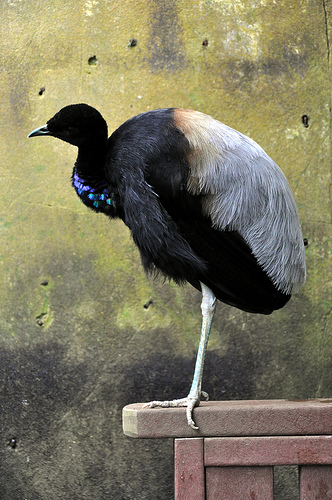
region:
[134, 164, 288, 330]
bird has black feathers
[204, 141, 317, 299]
bird has grey feathers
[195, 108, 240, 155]
bird has white feathers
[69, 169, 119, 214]
bird has blue feathers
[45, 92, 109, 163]
bird has black head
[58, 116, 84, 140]
bird has black eye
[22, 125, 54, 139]
bird has black beak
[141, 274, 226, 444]
bird has grey leg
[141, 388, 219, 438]
bird has grey talon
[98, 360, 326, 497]
bird on brown ledge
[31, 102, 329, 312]
A bird is black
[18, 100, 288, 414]
The bird is perched on the ledge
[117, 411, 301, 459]
The ledge is made of stone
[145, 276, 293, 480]
The bird has one leg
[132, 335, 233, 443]
The bird has claws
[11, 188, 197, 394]
The background wall is green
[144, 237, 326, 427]
the bird's leg is white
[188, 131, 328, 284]
The back of the bird is white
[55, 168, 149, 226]
The bird's neck is multicolored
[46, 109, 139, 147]
The bird's head is black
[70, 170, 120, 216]
the blue feathers on a bird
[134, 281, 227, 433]
the scaled legs of a bird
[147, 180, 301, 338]
the black feathers on a bird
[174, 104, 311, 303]
the white feathers on a bird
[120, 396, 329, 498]
the wooden arm of bench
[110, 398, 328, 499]
the wooden arm of a bench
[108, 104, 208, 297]
plumes of gray on a bird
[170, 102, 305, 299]
plumes of white on a bird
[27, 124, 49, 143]
the shiny beak of a bird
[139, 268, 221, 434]
the long legs of a bird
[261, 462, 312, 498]
Small gap between bricks.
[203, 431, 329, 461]
Horizontal brick on top.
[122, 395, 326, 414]
Big brick on top of the rest.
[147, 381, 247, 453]
Birds foot on top of brick.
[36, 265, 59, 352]
Small spot on top of window.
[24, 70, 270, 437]
Big bird on top of stand.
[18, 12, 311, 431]
Stained glass behind bird.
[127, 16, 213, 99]
Black shadow on the glass.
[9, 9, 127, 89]
Green shadow behind bird.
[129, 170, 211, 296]
Big grey feather on side of bird.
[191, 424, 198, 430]
Bottom most claw of a bird.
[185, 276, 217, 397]
Long grey white leg of a bird.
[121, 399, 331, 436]
Concrete ledge a birds leg is perched on.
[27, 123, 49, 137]
Grey beak of a bird.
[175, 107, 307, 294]
Grey section of back feathers.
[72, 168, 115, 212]
Blue and green blocks on a birds neck area.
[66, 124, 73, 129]
Black eye of a bird.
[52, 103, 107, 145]
Solid black head of a bird.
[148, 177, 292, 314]
Black feathers in the middle of the birds side section.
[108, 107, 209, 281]
Darker grey feathers on a large bird.